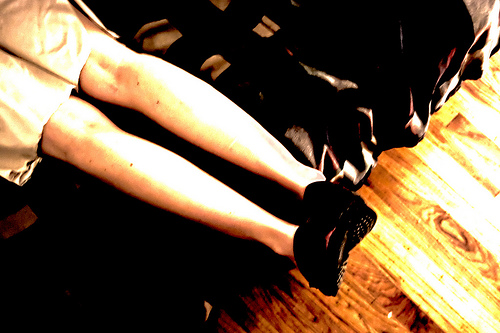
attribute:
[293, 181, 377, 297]
shoes — black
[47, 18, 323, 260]
legs — white, resting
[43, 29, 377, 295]
legs — laying down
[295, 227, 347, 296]
slipper — black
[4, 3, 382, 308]
legs — white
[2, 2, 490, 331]
blanket — black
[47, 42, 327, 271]
legs — pair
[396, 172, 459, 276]
floor — naturally-stained, wooden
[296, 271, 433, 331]
floor — dark brown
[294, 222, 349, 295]
shoe — black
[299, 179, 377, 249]
shoe — black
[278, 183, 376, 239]
slipper — black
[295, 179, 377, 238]
shoe — dark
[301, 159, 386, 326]
shoes — pair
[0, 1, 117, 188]
short — white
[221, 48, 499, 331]
floor — light brown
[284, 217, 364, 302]
shoes — black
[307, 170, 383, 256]
shoe — black